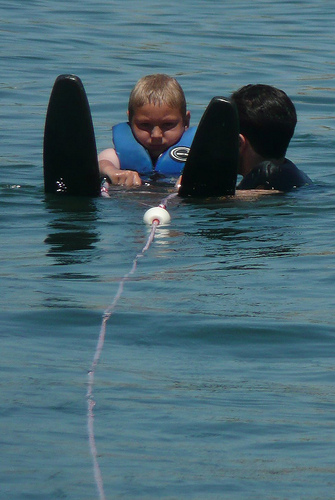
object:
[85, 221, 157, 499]
rope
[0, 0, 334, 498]
water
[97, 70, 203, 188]
boy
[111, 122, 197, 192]
life vest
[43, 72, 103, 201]
skis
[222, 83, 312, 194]
person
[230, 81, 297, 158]
short hair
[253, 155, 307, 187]
black top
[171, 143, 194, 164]
logo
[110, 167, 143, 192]
right hand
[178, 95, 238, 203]
water ski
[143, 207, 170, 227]
buoy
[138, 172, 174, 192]
handle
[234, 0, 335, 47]
ripples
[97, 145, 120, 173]
arm